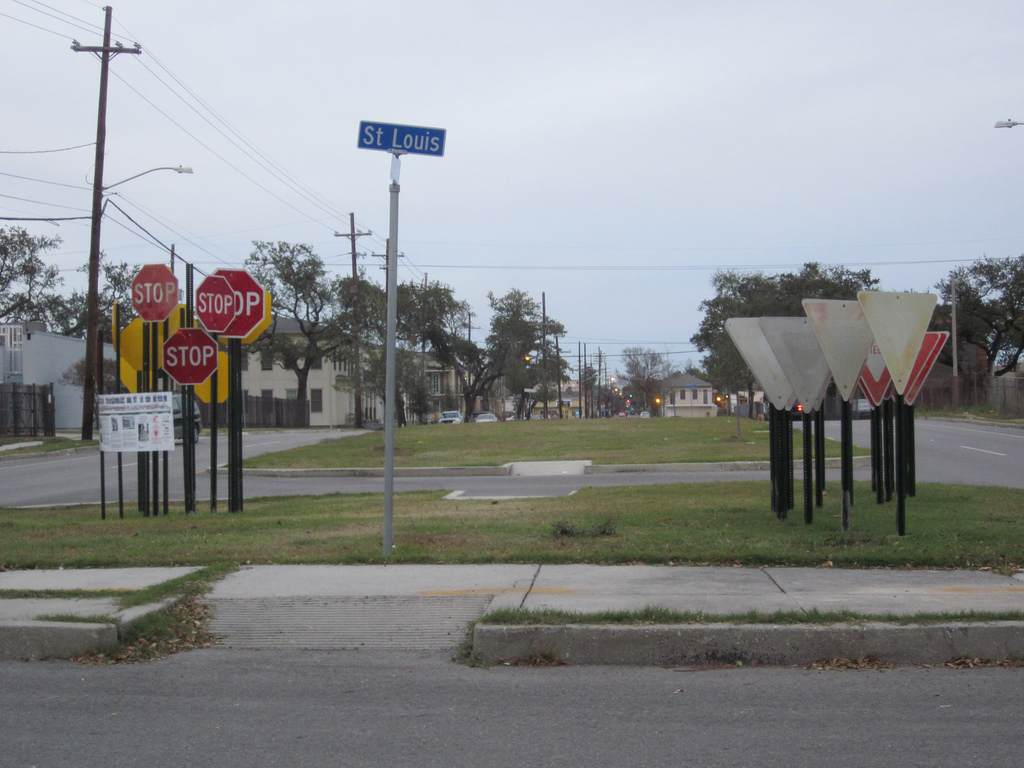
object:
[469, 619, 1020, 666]
curb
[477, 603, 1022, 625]
grass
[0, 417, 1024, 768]
ground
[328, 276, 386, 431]
tree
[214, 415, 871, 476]
lawn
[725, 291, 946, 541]
signs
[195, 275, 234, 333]
sign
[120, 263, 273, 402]
signs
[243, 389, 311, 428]
fence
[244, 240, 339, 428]
tree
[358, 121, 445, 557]
street sign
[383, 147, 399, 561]
pole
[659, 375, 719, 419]
house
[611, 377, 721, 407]
lights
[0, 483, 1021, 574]
lawn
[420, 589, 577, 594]
line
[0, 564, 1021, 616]
sidewalk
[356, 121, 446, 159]
sign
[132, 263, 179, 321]
stop sign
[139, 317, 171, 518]
pole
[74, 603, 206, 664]
leaves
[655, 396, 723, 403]
traffic lights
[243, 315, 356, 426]
house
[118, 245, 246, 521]
pole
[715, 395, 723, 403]
light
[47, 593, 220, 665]
gutter